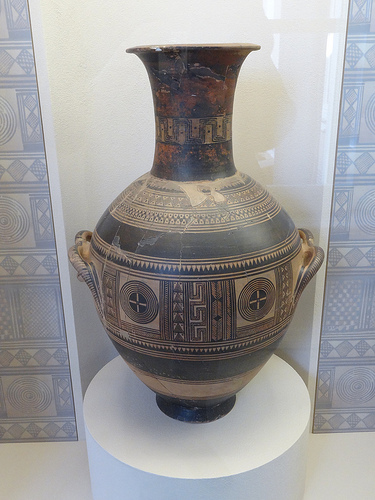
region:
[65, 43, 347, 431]
a vase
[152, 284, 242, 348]
a design on the vase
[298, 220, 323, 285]
left handle on the vase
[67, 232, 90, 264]
the right handle on the vase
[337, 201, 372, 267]
wallpaper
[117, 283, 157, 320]
a design that is brown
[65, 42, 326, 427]
ancient vase with patterns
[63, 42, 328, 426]
an ancient artifact in a museum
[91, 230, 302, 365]
row of patters on a vase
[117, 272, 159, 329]
circle patter on a vase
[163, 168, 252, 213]
worn spots on a vase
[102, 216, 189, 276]
cracks on an old pot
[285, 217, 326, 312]
the handle of an old vase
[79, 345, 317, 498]
white pedestal holding a vase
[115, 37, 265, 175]
the neck of an old vase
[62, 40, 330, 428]
a very old piece of pottery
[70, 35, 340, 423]
a vase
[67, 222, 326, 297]
the handles on vase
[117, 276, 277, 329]
the circles on the vase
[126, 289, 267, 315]
two crosses on vase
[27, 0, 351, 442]
the shiny insert for vase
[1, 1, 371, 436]
the blue and white designed wall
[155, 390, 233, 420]
the base of vase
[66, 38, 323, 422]
the big vase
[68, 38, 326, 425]
the brown vase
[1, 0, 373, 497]
a wall that has a display case in it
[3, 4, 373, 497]
a wall that is painted blue and white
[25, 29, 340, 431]
the vase has two handles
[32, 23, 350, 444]
a vase that has only one opening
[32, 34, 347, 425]
vase is behind glass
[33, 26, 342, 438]
this vase is very old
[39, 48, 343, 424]
vase has several different designs on it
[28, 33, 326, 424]
the vase has several circles on it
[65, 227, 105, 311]
handle on the left side of vase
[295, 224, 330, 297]
handle on the right side of vase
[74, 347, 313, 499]
white podium stand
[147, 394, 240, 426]
base of the vase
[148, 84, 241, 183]
neck of the vase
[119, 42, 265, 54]
rim of the vase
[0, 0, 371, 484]
wall behind the vase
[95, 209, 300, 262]
dark stripe on the vase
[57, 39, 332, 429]
vase on a podium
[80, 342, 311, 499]
a vase stand on the ground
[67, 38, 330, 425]
an old vase artifact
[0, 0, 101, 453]
a pattern on the wall of an art display